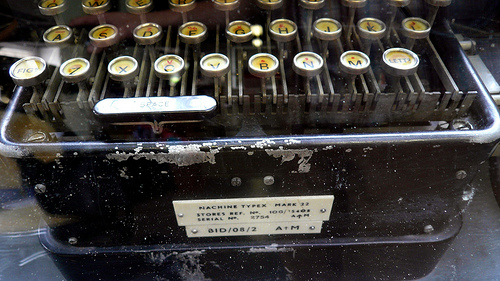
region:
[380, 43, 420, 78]
silver and orange key on an old typewriter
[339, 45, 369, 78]
silver and orange key on an old typewriter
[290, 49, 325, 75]
silver and orange key on an old typewriter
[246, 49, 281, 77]
silver and orange key on an old typewriter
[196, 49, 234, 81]
silver and orange key on an old typewriter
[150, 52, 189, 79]
silver and orange key on an old typewriter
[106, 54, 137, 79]
silver and orange key on an old typewriter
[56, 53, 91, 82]
silver and orange key on an old typewriter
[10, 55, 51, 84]
silver and orange key on an old typewriter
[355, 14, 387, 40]
silver and orange key on an old typewriter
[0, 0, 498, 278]
the old fashioned typewriter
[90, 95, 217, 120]
the space key on the typewriter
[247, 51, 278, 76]
the "B" key on the typewriter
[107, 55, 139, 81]
the "X" key on the typewriter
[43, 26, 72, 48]
the "A" key on the typewriter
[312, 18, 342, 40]
the "J" key on the typewriter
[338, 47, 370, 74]
the "M" key on the typewriter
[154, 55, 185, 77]
the "C" key on the typewriter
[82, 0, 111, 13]
the "W" key on the typewriter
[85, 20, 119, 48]
silver and orange key on an old typewriter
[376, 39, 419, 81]
this is a small plastic tin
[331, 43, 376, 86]
this is a small plastic tin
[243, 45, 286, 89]
this is a small plastic tin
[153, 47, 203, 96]
this is a small plastic tin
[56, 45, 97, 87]
this is a small plastic tin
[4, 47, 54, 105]
this is a small plastic tin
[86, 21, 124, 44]
this is a small plastic tin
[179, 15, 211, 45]
this is a small plastic tin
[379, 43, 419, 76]
silver and orange key of typewriter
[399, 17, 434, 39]
silver and orange key of typewriter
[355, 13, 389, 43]
silver and orange key of typewriter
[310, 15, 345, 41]
silver and orange key of typewriter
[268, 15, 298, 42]
silver and orange key of typewriter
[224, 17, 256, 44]
silver and orange key of typewriter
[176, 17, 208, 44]
silver and orange key of typewriter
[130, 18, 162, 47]
silver and orange key of typewriter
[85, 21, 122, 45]
silver and orange key of typewriter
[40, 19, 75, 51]
silver and orange key of typewriter